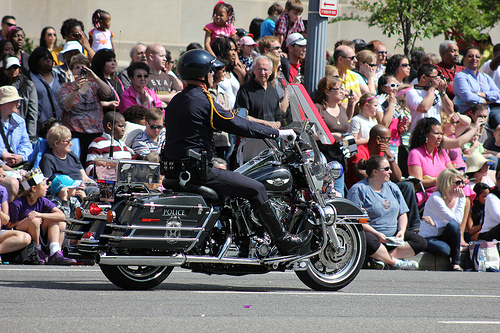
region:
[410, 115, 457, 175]
person in the crowd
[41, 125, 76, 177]
person in the crowd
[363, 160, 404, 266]
person in the crowd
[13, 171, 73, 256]
person in the crowd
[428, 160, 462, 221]
person in the crowd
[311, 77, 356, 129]
person in the crowd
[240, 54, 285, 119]
person in the crowd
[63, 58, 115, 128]
person in the crowd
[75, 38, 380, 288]
police officer riding a motorcycle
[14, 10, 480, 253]
spectators on sidewalk to watch event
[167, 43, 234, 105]
officer wearing a motorcycle helmet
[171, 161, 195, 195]
silver handcuffs attached to police officers belt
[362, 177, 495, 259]
people sitting on curb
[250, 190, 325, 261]
police oficer wearing black boots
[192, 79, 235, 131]
decorative yellow rope on police officers uniform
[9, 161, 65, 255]
child wearing a gold crown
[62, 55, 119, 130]
woman taking a photograph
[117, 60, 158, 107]
woman wearing black sun glasses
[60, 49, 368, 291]
a police officer on motorcycle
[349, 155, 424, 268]
a spectator seated on curb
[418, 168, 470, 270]
a spectator seated on curb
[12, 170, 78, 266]
a spectator seated on curb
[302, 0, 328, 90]
a grey street light pole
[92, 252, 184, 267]
a chrome exhaust pipe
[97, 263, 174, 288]
a motorcycle rear tire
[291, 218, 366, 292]
a motorcycle front tire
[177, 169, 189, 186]
a pair of handcuffs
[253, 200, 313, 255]
a black leather motorcycle boot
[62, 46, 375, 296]
a policeman is riding a motorcycle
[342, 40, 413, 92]
the people are wearing sunglasses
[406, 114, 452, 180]
the lady with the dark hair is wearing a pink shirt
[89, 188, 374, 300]
the motorcycle has 2 tires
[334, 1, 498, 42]
a green tree in the background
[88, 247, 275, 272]
the motorcycle exhaust pipe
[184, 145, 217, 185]
the police officer's gun is in the holster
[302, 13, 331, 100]
a blue column among the seats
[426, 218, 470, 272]
the lady wearing the white blouse is wearing blue jeans too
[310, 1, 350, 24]
a red arrow giving directions to the left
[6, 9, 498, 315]
a crowd of people are on the side of the road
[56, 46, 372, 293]
a motorcycle policeman is driving down the road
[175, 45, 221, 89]
the policeman has a black helmet on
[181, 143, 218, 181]
a gun is in the policeman's holster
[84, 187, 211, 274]
saddle bags are on each side of the wheel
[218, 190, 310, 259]
the man has black boots on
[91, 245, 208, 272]
the exhaust is chrome on the cycle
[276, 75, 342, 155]
a windshield is on the motorcycle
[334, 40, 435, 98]
people in the crowd have sunglasses on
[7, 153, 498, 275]
people are sitting on the curb